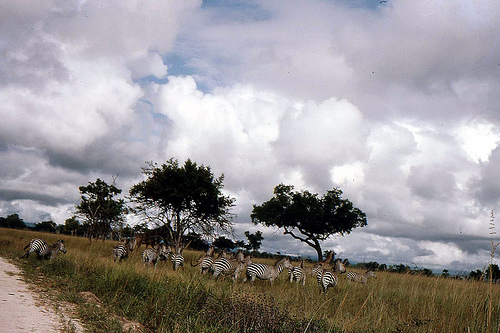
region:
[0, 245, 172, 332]
white dusty dirt road near grassy field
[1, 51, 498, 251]
long row of thick white fluffy clouds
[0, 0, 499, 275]
blue and white sky filled with thick white fluffy clouds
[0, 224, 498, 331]
large grassy field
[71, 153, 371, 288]
dark green trees in large grassy field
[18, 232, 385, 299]
large group of black and white striped zebras walking through a large grassy field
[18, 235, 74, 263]
black and white zebra running into large grassy field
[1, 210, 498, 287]
row of dark green trees bordering large grassy field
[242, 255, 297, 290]
black and white striped zebra standing in tall grass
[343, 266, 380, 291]
black and white striped zebra standing in tall grass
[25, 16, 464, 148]
this is the sky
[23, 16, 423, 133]
the sky is full of clouds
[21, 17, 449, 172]
the clouds are big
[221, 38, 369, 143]
the clouds are white in color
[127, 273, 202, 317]
this is the grass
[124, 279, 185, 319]
the grass is green in color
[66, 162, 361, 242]
these are some trees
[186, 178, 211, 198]
the leaves are green in color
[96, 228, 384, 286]
these are some zebras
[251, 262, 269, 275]
the fur is black and white in color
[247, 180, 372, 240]
the green tree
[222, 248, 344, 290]
zebras in a field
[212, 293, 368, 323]
the grass is tall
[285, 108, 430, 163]
the clouds are white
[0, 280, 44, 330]
the road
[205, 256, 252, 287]
the zebras are black and white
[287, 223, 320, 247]
a tree branch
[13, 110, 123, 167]
the cloud is grey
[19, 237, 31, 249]
a zebras tail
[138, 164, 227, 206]
the leaves are green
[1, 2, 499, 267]
thick white clouds in the sky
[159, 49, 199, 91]
patch of blue sky poking through the clouds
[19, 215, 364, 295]
a herd of zebras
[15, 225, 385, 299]
zebras standing on the grasss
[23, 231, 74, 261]
black and white zebra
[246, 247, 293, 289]
side profile of a zebra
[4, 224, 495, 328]
tall grass on the ground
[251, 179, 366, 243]
dark tree top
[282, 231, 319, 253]
long branch sticking out of the tree trunk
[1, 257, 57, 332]
dirt alongside the field of grass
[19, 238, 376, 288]
the herd of zebras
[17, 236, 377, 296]
the animals in the tall grass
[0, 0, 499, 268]
the thick clouds in the sky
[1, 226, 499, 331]
the tall grass on the ground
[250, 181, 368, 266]
the tree near the zebras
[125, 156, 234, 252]
the tree near the zebras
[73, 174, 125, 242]
the tree near the zebras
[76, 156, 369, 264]
the trees near the zebras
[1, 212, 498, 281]
the trees in the distance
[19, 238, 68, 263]
the zebra walking into the tall grass